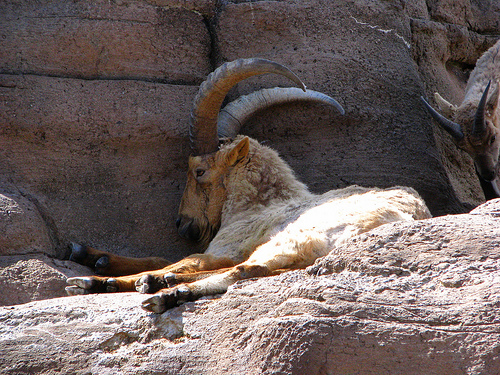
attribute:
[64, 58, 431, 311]
animal — relaxing, goat, shady, laying, white, yak, tan, furry, ram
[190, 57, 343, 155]
horns — short, a pair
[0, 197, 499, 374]
cliff face — weathered, rocky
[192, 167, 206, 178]
eye — brown, yellow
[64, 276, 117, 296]
hoof — cloven, gray, present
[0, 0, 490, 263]
wall — rocky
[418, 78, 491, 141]
horns — black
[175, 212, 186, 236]
nose — brown, black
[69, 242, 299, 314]
legs — brown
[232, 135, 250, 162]
ears — pointy